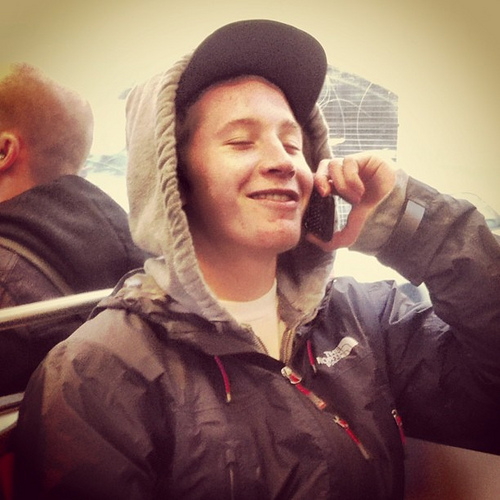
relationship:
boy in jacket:
[21, 19, 498, 494] [56, 275, 456, 473]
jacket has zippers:
[64, 287, 453, 492] [277, 351, 399, 465]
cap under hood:
[184, 14, 325, 105] [103, 60, 344, 304]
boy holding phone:
[21, 19, 498, 494] [295, 180, 344, 253]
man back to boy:
[8, 71, 119, 338] [21, 19, 498, 494]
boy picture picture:
[21, 19, 498, 494] [2, 3, 488, 497]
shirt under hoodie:
[230, 291, 313, 349] [122, 57, 336, 319]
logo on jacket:
[317, 330, 358, 365] [57, 268, 374, 482]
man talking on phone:
[188, 80, 325, 260] [295, 171, 341, 245]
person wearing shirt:
[166, 90, 336, 390] [208, 275, 314, 387]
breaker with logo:
[64, 259, 424, 463] [322, 330, 360, 368]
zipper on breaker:
[274, 360, 387, 472] [18, 259, 424, 487]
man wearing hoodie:
[100, 16, 403, 466] [116, 44, 350, 305]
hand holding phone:
[311, 153, 409, 240] [295, 171, 341, 245]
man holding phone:
[127, 32, 405, 410] [292, 178, 342, 239]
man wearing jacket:
[117, 21, 386, 486] [43, 280, 423, 479]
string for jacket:
[203, 351, 240, 408] [43, 280, 423, 479]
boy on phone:
[21, 19, 498, 494] [296, 193, 338, 245]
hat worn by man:
[147, 20, 336, 106] [130, 25, 390, 445]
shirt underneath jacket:
[217, 278, 306, 368] [62, 284, 382, 462]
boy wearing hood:
[21, 19, 498, 494] [122, 65, 336, 316]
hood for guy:
[12, 188, 130, 283] [12, 60, 130, 296]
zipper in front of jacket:
[217, 443, 261, 495] [90, 324, 292, 442]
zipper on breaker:
[273, 358, 370, 452] [18, 259, 424, 487]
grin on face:
[234, 184, 319, 217] [203, 91, 330, 249]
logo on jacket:
[309, 328, 363, 376] [133, 328, 329, 434]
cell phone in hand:
[307, 164, 348, 251] [311, 146, 409, 254]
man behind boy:
[10, 67, 105, 442] [21, 19, 498, 494]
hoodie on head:
[110, 69, 237, 354] [90, 61, 343, 357]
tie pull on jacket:
[199, 360, 240, 410] [115, 361, 252, 439]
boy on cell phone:
[129, 79, 319, 419] [307, 164, 348, 251]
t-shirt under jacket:
[235, 290, 300, 362] [104, 322, 299, 441]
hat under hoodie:
[147, 20, 336, 106] [103, 48, 263, 287]